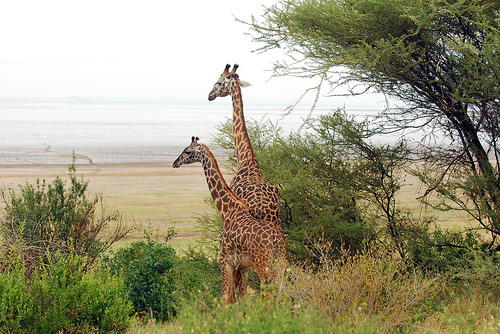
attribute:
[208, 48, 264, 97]
horns — tall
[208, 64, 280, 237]
giraffe — tall, short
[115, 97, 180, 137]
water — large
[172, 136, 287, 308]
giraffe — shorter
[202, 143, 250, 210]
mane — short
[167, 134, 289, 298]
giraffe — shorter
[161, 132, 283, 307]
animal — brown and white